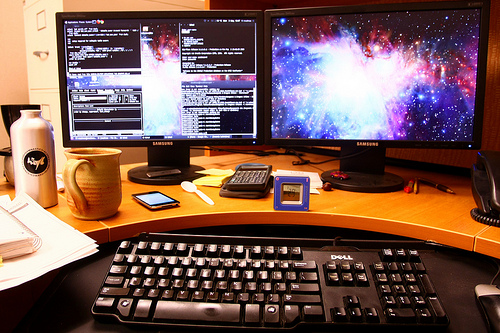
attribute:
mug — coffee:
[55, 119, 134, 231]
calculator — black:
[212, 157, 367, 232]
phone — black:
[473, 151, 498, 223]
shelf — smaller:
[2, 224, 498, 331]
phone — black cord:
[471, 145, 498, 225]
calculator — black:
[212, 150, 278, 207]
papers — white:
[0, 190, 105, 297]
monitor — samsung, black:
[56, 12, 267, 145]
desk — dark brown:
[1, 147, 493, 277]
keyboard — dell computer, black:
[95, 236, 443, 331]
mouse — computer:
[473, 282, 498, 332]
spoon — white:
[180, 175, 215, 202]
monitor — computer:
[10, 13, 255, 177]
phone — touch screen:
[127, 182, 182, 213]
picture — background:
[276, 18, 479, 137]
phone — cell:
[124, 182, 176, 217]